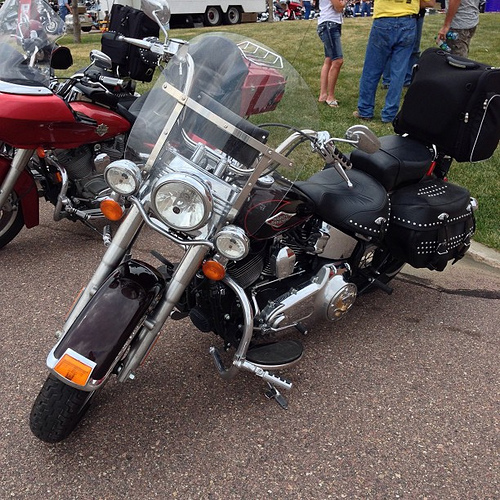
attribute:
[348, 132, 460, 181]
rider seat — second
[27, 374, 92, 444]
tire — the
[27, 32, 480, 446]
motorcycle — a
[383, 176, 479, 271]
side bags — decorative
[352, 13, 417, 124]
jeans — blue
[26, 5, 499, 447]
motorcycle — the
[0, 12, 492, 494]
ground — the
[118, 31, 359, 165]
bars — the, handle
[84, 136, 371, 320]
motorcycle — the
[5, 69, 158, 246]
motorcycle — red, the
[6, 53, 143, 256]
motorcyle — framed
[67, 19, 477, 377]
motorcycle — harley, davidson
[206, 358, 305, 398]
kickstand — the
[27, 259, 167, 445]
tire — motorcycle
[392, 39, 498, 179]
suitecase — black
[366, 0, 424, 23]
shirt — yellow